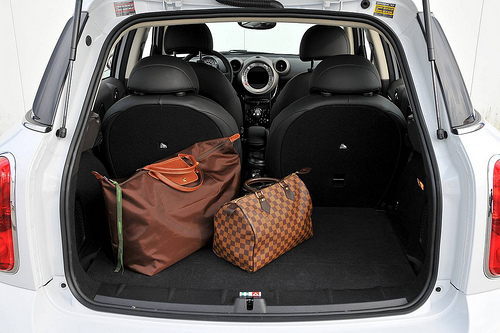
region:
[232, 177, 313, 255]
smaller brown bag with checkerboard print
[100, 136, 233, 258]
big brown purse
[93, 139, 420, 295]
trunk of car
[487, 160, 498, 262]
right rear tail light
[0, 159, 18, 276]
left rear tail light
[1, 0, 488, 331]
white car with trunk door open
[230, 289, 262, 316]
black latch for trunk door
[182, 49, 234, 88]
black driver's steering wheel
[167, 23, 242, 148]
driver's seat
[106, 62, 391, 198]
black leather back seats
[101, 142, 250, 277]
The plain brown bag.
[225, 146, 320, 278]
The small patterned designed bag.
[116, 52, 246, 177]
The left back passenger seat.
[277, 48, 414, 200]
The right back passenger seat.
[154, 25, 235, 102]
The driver seat and head rest.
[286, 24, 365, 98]
The passenger seat and head rest in the front.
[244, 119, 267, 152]
The center console between the two front seats.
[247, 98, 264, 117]
The black gear shift.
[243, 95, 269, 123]
The panel of buttons in front of the gear shift.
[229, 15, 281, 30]
The rear view mirror of the vehicle.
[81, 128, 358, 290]
two bags in the trunk of a car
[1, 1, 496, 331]
car with its trunk open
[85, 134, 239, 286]
dark brown bag with light brown handles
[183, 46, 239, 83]
steering wheel is on the left side of the car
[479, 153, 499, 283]
long red tail light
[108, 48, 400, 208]
only two seats in the back of the car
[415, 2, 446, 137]
thin rod holding up the trunk door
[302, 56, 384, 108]
black headrest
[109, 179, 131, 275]
long, green strip hanging over the bag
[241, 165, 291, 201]
handles leaning over to one side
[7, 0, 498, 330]
a white SUV vehicle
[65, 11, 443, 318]
an opened vehicle trunk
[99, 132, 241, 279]
a dark brown bag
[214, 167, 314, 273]
a brown checkered bag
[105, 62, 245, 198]
vehicle rear driver's side seat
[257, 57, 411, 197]
vehicle rear passenger's side seat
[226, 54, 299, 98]
vehicle front dashboard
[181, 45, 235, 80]
a black car steering wheel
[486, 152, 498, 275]
right rear brake light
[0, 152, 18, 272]
left rear brake light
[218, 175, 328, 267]
a brown and rust colored carry on bag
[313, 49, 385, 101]
a gray headrest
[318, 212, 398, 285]
the trunk floor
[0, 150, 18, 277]
a red tail light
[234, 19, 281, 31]
a rearview mirror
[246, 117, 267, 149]
a black armrest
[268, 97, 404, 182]
the back of the rear vehicle seat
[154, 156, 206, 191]
rust colored luggage handles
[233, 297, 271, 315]
a gray trunk latch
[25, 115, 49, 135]
chrome molding on the vehicle